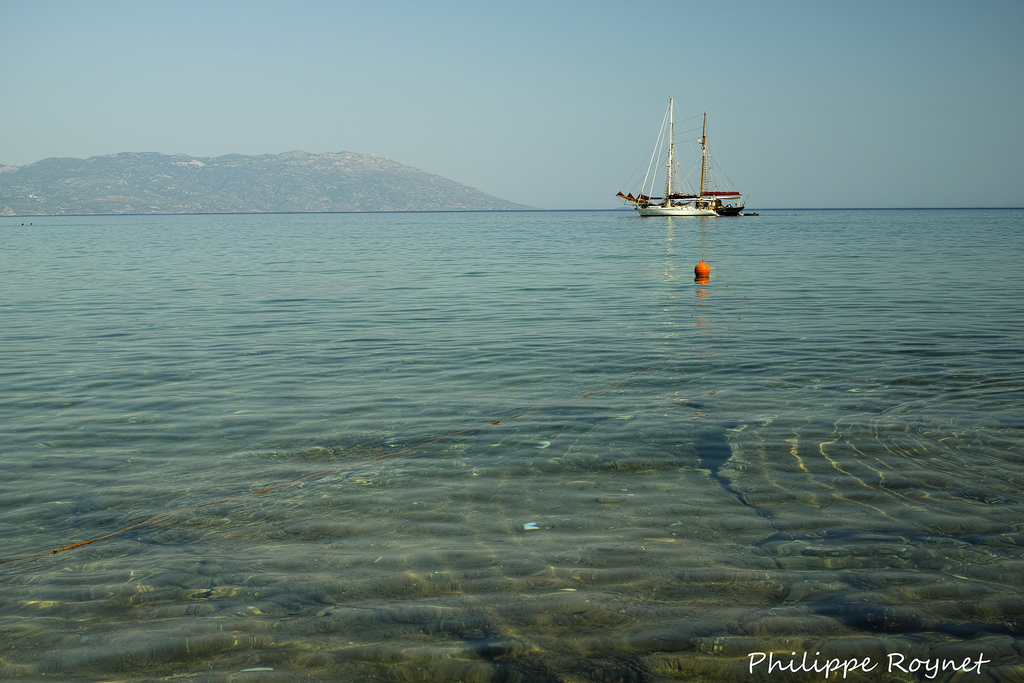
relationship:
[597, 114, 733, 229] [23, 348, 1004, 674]
boat on water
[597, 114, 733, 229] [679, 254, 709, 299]
boat behind buoy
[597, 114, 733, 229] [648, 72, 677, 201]
boat has mast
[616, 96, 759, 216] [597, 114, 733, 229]
boat near boat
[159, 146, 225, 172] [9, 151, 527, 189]
house on hill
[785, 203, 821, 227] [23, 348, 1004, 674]
swimmers in water